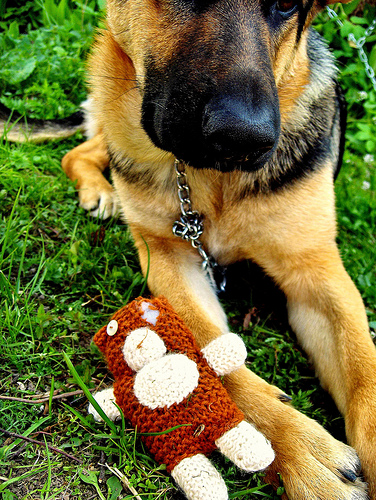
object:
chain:
[170, 154, 228, 293]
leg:
[61, 129, 119, 220]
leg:
[252, 230, 375, 496]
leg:
[131, 231, 368, 500]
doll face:
[103, 294, 193, 376]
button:
[104, 319, 118, 338]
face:
[107, 0, 349, 174]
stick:
[0, 384, 96, 405]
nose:
[204, 111, 279, 164]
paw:
[269, 388, 370, 500]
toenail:
[275, 388, 292, 403]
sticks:
[0, 425, 85, 464]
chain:
[324, 5, 375, 87]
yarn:
[87, 294, 275, 500]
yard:
[0, 0, 375, 499]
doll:
[86, 294, 275, 499]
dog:
[0, 0, 375, 499]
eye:
[274, 0, 299, 16]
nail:
[333, 465, 357, 483]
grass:
[0, 0, 375, 499]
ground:
[0, 0, 375, 498]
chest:
[146, 159, 302, 249]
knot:
[171, 208, 206, 246]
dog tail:
[0, 101, 85, 145]